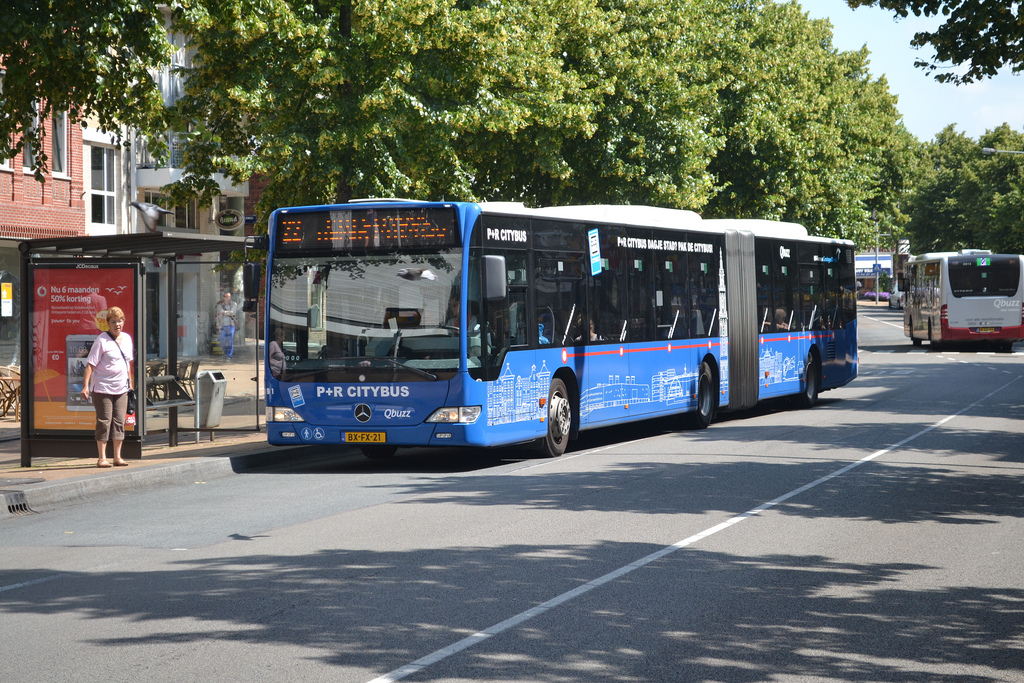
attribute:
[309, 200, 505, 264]
lcd — orange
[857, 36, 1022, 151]
sky — blue, clear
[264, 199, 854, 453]
bus — black , blue 